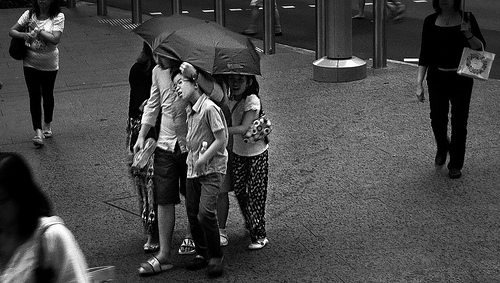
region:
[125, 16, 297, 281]
the people are under the umbrella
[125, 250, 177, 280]
the man is wearing a sandal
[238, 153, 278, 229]
the pants are poka dotted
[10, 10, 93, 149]
the woman is walking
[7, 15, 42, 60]
the woman is carrying a purse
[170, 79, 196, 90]
the boy is wearing glasses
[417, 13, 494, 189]
the woman is carrying a paper bag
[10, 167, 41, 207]
the woman has hair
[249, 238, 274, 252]
the girl is wearing a white shoe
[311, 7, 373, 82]
the pillar is big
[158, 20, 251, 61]
this is a umbrella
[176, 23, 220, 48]
the umbrella is black in color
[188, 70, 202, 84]
this is a watch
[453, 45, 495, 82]
this is a bag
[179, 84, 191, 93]
the boy is light skinned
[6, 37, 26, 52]
this is a handbag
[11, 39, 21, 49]
the handbag is black in color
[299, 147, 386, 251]
this is the ground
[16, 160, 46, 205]
this is the hair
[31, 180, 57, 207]
the hair is long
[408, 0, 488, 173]
A woman in a black shirt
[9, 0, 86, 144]
A woman in a white shirt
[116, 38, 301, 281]
A group of people under an umbrella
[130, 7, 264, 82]
An umbrella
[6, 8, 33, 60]
A black purse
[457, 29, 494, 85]
A white bag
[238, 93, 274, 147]
A multi colored handbag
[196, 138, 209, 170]
A drinking bottle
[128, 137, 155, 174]
A large water bottle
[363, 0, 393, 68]
A metal pylon on the sidewalk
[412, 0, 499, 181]
This is a person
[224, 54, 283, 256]
This is a person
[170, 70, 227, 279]
This is a person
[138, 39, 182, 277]
This is a person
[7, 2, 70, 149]
This is a person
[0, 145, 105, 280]
This is a person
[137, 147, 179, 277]
This is a leg of a person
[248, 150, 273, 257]
This is a leg of a person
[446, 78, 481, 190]
This is a leg of a person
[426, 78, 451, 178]
This is a leg of a person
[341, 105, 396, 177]
part of a floor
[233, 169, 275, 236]
part of a trouser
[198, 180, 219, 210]
part of a trouser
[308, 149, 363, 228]
part of a floor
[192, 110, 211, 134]
part of a shirt